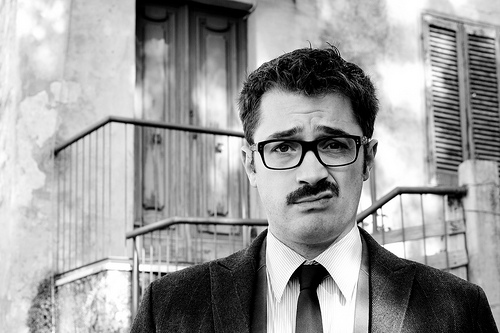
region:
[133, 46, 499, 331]
A man looking at the camera.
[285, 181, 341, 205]
The man's moustache.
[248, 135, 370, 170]
The man's glasses.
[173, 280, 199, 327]
Part of the man's jacket.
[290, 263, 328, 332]
Part of a black tie.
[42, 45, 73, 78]
Part of the building.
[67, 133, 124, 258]
Part of a railing.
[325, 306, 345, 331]
Part of a white shirt.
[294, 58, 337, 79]
part of the man's dark hair.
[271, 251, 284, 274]
part of a white collar.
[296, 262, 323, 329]
black tie on man's neck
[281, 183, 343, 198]
black mustache on man's face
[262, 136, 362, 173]
black glasses on man's face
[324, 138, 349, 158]
left eye of the man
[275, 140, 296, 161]
the man's right eye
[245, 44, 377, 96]
black hair on man's hair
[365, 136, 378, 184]
the man's left ear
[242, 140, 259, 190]
the man's right ear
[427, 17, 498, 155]
shutters over the windows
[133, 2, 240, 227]
door to the building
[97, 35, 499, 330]
man wearing a suit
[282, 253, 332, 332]
tie hangign down from the neck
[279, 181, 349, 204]
mustache growing above the lips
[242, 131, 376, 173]
black glasses on the face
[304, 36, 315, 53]
strands of hair sticking up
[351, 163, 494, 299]
railing along the stairs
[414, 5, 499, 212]
shutters on the window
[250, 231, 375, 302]
collar is down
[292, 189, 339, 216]
side of the mouth is lifted up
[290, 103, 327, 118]
line in the forehead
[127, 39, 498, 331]
man standing in suit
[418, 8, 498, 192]
building has wooden window shutters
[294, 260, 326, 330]
man has black tie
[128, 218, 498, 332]
man has black coat and tie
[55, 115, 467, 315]
metal railings behind person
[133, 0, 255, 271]
wooden doors on house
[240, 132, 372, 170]
the eyeglasses are black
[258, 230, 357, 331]
white button up shirt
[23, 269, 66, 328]
plant on wall section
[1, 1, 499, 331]
photo is shot in black and white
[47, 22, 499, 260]
this man did not want his picture taken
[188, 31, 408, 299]
he looks very dissapointed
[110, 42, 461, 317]
he looks very agitated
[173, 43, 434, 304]
he does not want to be bothered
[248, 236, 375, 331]
he is wearing a tie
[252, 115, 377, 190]
he has on glasses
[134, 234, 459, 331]
he is wearing suit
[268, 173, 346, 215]
he has on a moustache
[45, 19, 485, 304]
this photo is black and white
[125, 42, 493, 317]
this guy expression says that he does not care